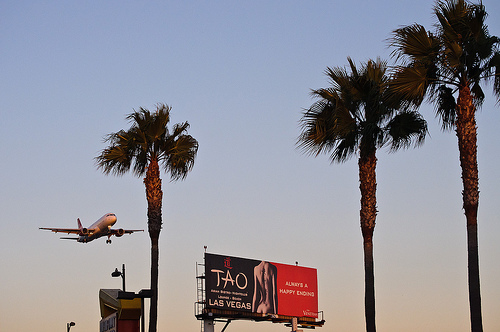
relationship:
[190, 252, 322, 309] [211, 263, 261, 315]
sign has lettering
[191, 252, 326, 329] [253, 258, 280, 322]
sign has person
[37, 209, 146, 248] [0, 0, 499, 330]
airplane in sky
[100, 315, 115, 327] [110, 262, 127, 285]
sign beneath lamp